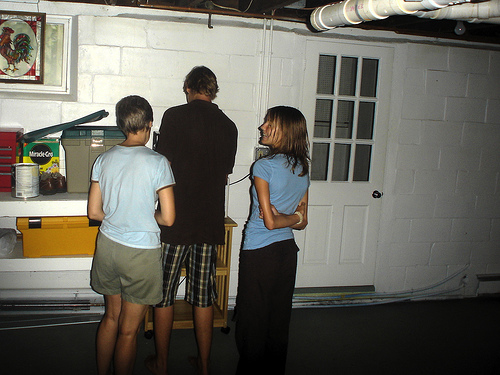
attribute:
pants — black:
[235, 235, 300, 371]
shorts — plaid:
[161, 238, 221, 313]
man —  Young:
[148, 62, 238, 372]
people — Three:
[87, 63, 311, 373]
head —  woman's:
[256, 104, 306, 148]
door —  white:
[290, 42, 396, 289]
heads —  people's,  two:
[114, 93, 154, 134]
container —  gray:
[60, 123, 127, 194]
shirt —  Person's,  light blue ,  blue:
[242, 149, 308, 250]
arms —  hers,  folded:
[256, 176, 311, 227]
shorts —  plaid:
[155, 242, 219, 305]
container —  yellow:
[16, 216, 99, 256]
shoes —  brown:
[39, 171, 69, 191]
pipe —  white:
[307, 2, 496, 32]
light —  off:
[450, 18, 467, 38]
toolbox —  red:
[0, 130, 15, 191]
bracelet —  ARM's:
[293, 211, 303, 227]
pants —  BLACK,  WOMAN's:
[238, 238, 298, 373]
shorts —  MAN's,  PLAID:
[160, 239, 216, 308]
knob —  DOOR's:
[372, 189, 380, 199]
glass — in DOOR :
[334, 101, 354, 138]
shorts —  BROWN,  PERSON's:
[90, 232, 166, 305]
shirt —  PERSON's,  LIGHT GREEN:
[90, 143, 176, 249]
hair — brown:
[175, 64, 220, 96]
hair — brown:
[280, 102, 304, 162]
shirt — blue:
[247, 148, 310, 243]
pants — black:
[234, 236, 294, 371]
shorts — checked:
[157, 217, 221, 313]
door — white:
[299, 38, 393, 318]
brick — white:
[441, 90, 491, 126]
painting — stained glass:
[0, 11, 49, 92]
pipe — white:
[311, 1, 496, 22]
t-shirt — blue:
[243, 150, 309, 250]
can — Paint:
[14, 158, 42, 199]